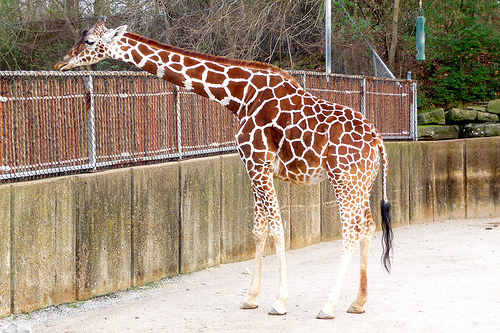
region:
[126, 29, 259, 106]
neck of the giraffe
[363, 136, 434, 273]
tail of the giraffe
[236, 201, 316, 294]
legs of the giraffe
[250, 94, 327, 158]
white lines on the giraffe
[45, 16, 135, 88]
head of the giraffe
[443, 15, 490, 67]
trees in the distance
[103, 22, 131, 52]
ear of the animal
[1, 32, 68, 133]
fence in front of animal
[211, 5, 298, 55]
branches of the tree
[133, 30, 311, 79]
hair on back of giraffe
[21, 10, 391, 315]
A giraffe next to a fence.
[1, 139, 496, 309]
A concrete base of a fence.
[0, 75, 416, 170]
Metal posts along the fence.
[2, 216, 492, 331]
The ground is dirt.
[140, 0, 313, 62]
Tree limbs behind the fence.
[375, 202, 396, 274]
Black hair on the end of a giraffe's tail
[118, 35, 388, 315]
The giraffe has orange spots.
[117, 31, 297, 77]
A mane along the giraffe's neck.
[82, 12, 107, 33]
Ossicones on top of the giraffe's head.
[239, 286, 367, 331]
The giraffe is standing on dirt.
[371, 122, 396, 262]
tail of a giraffe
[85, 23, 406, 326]
tall brown and white giraffe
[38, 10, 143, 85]
head of a giraffe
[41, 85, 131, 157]
fence near a giraffe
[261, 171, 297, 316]
leg of a giraffe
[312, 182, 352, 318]
leg of a griaffe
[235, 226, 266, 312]
leg of a giraffe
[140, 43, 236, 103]
long neck of a giraffe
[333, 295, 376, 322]
huff of a giraffe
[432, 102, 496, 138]
rocks near a fence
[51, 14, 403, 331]
A giraffe with brown spots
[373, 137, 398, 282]
A giraffe's tail with black hair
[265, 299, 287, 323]
A giraffe's front hoof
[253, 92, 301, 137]
Brown spots on a giraffe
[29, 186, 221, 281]
A brown concrete wall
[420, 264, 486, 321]
A light brown dirt ground surface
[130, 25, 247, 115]
A giraffe's long neck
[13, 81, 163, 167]
A metal chain link fence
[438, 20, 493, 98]
Green trees in the background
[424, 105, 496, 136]
A pile of gray stones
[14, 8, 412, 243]
giraffe in the photo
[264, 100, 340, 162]
brown spots on the giraffe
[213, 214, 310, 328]
legs of the giraffe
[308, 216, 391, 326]
back legs of the giraffe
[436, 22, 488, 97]
green leaves in the background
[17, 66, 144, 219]
fence next to the giraffe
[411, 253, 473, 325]
dirt on the ground